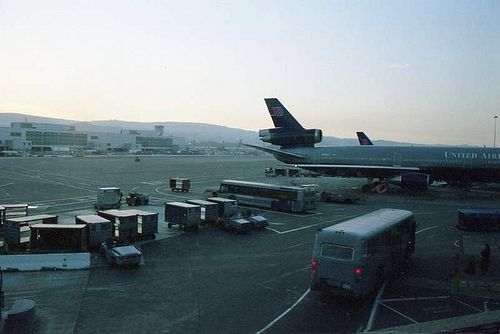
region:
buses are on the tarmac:
[220, 169, 424, 298]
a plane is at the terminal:
[237, 93, 497, 202]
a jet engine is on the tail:
[249, 90, 327, 155]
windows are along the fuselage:
[321, 149, 496, 170]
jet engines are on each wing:
[378, 160, 440, 194]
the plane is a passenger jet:
[246, 96, 495, 198]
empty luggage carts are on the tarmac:
[3, 175, 250, 264]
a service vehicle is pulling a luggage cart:
[91, 180, 154, 210]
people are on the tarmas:
[441, 225, 494, 286]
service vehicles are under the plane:
[290, 173, 392, 205]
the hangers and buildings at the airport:
[1, 125, 238, 162]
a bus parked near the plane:
[203, 165, 318, 221]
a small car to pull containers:
[97, 238, 152, 272]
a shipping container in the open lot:
[149, 165, 211, 197]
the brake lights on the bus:
[302, 250, 372, 292]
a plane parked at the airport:
[242, 107, 493, 186]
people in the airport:
[451, 234, 497, 284]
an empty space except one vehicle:
[73, 149, 205, 181]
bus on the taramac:
[288, 189, 438, 321]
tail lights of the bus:
[291, 255, 368, 278]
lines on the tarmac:
[358, 273, 478, 330]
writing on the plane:
[435, 142, 495, 164]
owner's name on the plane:
[436, 145, 499, 173]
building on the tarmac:
[3, 115, 94, 167]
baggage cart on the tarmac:
[161, 169, 196, 194]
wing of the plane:
[275, 154, 422, 182]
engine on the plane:
[376, 166, 444, 206]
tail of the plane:
[235, 90, 312, 189]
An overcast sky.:
[10, 1, 494, 93]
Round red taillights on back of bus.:
[310, 257, 366, 287]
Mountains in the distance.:
[5, 108, 268, 140]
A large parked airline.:
[259, 96, 499, 186]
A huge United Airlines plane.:
[260, 88, 491, 182]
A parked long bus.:
[220, 177, 315, 214]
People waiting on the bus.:
[445, 239, 492, 275]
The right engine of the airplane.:
[387, 172, 439, 188]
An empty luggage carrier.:
[167, 178, 192, 193]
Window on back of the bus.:
[321, 239, 353, 263]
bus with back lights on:
[307, 223, 424, 306]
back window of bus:
[320, 235, 360, 266]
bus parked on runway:
[315, 203, 425, 310]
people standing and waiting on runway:
[444, 232, 499, 279]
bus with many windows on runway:
[216, 166, 320, 213]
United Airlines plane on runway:
[252, 90, 498, 195]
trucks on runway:
[212, 194, 267, 232]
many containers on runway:
[5, 190, 269, 274]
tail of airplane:
[254, 93, 327, 151]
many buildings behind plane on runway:
[1, 104, 241, 160]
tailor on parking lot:
[126, 205, 161, 236]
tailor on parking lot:
[99, 206, 137, 236]